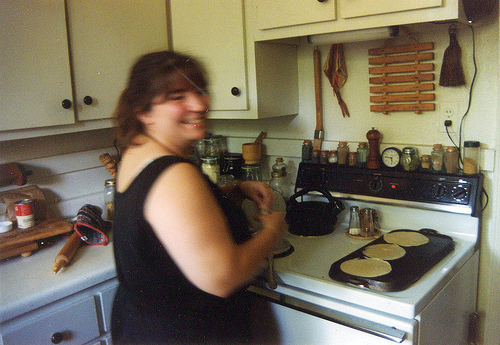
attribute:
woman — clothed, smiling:
[111, 49, 286, 344]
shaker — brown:
[360, 207, 373, 235]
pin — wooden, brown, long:
[51, 234, 79, 273]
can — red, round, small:
[15, 200, 36, 230]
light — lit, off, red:
[392, 185, 396, 190]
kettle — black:
[286, 186, 346, 237]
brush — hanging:
[311, 49, 325, 153]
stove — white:
[249, 162, 483, 344]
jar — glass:
[267, 156, 292, 199]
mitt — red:
[74, 202, 113, 248]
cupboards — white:
[0, 2, 462, 143]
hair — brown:
[110, 51, 208, 144]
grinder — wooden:
[365, 124, 382, 169]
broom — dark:
[439, 25, 464, 87]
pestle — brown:
[240, 129, 268, 164]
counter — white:
[0, 195, 117, 325]